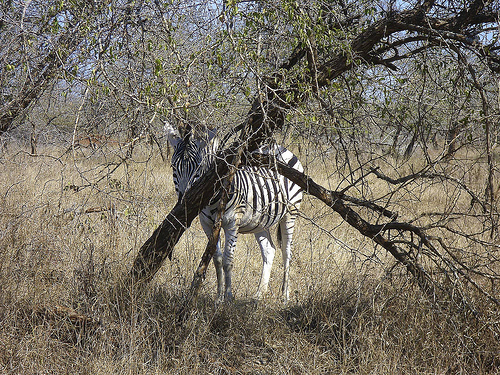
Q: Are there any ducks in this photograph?
A: No, there are no ducks.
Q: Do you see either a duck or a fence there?
A: No, there are no ducks or fences.